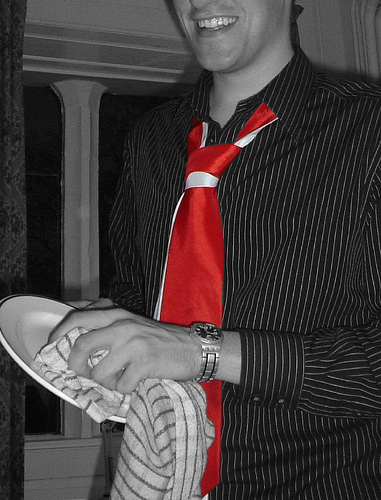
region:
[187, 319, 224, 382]
a man's silver wristwatch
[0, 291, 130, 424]
part of a white plate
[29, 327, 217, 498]
a black and white rag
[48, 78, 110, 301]
a tall white post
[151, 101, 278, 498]
a long red and white tie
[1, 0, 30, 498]
part of a long curtain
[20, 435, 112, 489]
part of a white window sill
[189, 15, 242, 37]
the mouth of a man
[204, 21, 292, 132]
the neck of a man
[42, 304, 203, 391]
the hand of a man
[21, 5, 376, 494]
Black and white photo with a red tie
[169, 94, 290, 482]
The tie is red and white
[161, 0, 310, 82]
A smiling man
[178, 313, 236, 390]
watch on the man's wrist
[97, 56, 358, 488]
The man's shirt is striped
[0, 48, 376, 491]
Man standing in front of a window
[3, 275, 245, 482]
The man is drying a dish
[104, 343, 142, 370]
No wedding ring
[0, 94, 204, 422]
Photo taken at night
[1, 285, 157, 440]
The plate is round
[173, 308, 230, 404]
Thick metal watch with a black face on a man's wrist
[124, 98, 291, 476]
A thick red and white tie being worn by a man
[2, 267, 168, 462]
A white plate with a black rim being cleaned by a man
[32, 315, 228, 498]
Striped dish cloth being used by a person to clean a dish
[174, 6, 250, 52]
Chin and white teeth of a person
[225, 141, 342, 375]
Black and white pinstripe button down shirt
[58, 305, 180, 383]
A man's hand holding a plate and dish towel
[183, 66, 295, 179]
Collar of a black and white pinstripe shirt with a tie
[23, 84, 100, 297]
Dark window with light colored side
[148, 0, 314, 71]
Person smiling and showing their teeth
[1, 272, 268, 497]
the hand is holding a towel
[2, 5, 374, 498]
the man is wiping a dish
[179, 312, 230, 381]
the man is wearing a watch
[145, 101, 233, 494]
he is wearing a tie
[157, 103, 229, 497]
the tie is red and white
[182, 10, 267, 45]
he is smiling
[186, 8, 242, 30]
his teeth are white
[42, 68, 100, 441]
a pillar behind the man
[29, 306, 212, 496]
the towel is striped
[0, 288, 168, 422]
the plate is round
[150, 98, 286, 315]
man wearing red tie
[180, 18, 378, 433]
man wearing dress shirt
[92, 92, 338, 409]
man wearing a watch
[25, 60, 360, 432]
man holding a towel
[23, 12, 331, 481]
man holding a plate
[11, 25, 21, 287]
curtain on a tall window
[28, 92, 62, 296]
tall window in a room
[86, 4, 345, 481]
man drying a plate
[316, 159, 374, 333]
stripes on a shirt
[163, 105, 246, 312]
large red and white tie